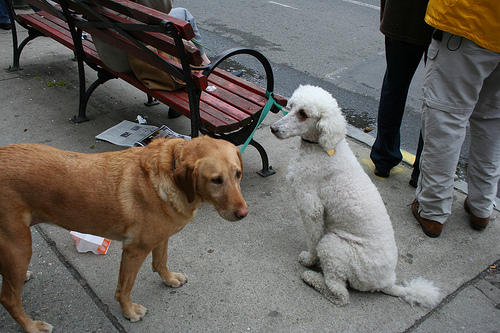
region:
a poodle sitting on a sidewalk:
[270, 86, 442, 310]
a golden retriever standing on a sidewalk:
[1, 133, 247, 330]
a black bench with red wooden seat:
[8, 0, 283, 172]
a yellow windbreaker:
[426, 0, 498, 51]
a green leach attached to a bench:
[239, 92, 288, 150]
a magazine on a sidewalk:
[95, 115, 193, 152]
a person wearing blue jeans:
[372, 24, 424, 171]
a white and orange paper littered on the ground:
[68, 230, 110, 253]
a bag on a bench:
[126, 39, 212, 89]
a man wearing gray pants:
[417, 30, 497, 223]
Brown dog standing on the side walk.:
[2, 130, 254, 300]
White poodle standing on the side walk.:
[275, 85, 406, 310]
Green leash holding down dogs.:
[259, 78, 297, 160]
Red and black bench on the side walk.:
[172, 45, 249, 137]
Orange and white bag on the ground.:
[68, 229, 111, 259]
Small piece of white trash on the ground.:
[110, 105, 150, 126]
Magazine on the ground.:
[98, 109, 163, 146]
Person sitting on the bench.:
[77, 0, 212, 76]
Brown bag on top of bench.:
[127, 23, 229, 94]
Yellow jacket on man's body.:
[413, 0, 480, 27]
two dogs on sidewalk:
[2, 83, 442, 323]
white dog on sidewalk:
[270, 83, 448, 311]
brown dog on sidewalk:
[3, 127, 276, 327]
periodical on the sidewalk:
[103, 110, 188, 160]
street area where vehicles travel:
[258, 11, 367, 66]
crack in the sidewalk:
[446, 280, 471, 308]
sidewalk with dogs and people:
[204, 248, 271, 323]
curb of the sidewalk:
[353, 123, 368, 150]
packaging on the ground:
[56, 228, 118, 263]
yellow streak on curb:
[405, 146, 415, 171]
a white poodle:
[262, 75, 452, 316]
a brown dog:
[1, 113, 270, 331]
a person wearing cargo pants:
[418, 28, 494, 265]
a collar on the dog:
[294, 133, 340, 162]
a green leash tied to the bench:
[233, 80, 281, 162]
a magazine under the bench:
[97, 105, 181, 152]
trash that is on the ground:
[57, 227, 115, 261]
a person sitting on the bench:
[103, 2, 214, 80]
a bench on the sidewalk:
[63, 5, 276, 152]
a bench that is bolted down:
[68, 1, 283, 176]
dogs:
[1, 78, 451, 331]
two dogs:
[2, 83, 452, 328]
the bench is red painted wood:
[3, 0, 283, 180]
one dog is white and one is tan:
[0, 83, 452, 332]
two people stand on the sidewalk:
[374, 1, 499, 243]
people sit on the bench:
[25, 2, 266, 134]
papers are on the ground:
[60, 108, 212, 265]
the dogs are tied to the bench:
[0, 70, 453, 326]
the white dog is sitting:
[255, 72, 457, 317]